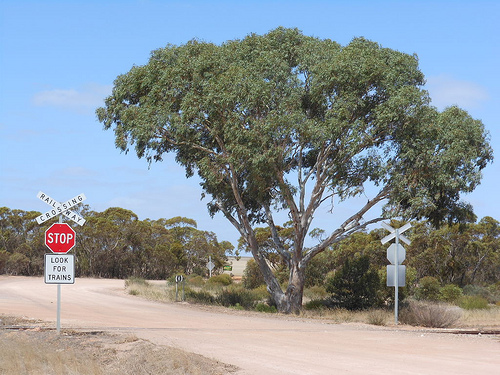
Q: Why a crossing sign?
A: Train track.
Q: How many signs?
A: Two.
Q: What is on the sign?
A: Look for trains.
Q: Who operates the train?
A: The engineer.